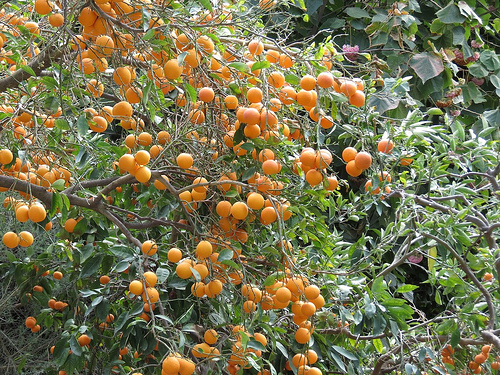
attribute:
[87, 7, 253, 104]
branches — leaveless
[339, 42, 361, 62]
purple leaf — tiny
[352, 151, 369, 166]
fruit — small, bunch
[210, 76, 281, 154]
orange — bunch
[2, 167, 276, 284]
branch — long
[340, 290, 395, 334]
leaves — green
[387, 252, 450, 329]
hole — dark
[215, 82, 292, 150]
oranges — different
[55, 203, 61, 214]
brown spot — tiny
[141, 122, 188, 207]
vine — brown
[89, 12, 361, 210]
orange fruits — hanging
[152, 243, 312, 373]
orange fruits — hanging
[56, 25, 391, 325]
stuff — orange, green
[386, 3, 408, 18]
brown leaves — small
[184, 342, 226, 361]
leaf — small, green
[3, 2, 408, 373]
fruit — orange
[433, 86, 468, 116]
dead blossoms — brown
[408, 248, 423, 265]
petal — purple, small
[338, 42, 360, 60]
blossom — purple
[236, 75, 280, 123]
fruit — orange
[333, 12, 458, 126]
leaves — green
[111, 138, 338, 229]
branch — small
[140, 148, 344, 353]
things — orange